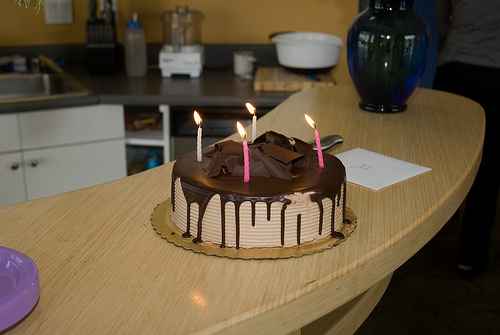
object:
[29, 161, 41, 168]
hardware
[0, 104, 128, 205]
cabinet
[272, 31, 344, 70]
bowl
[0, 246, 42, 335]
plastic plates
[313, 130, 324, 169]
candle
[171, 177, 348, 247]
icing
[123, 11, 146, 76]
baby bottle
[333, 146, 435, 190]
envelope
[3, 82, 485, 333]
bar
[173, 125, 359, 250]
birthday cake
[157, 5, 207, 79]
food processor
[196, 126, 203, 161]
candle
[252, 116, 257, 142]
candle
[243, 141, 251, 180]
candle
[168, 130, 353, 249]
chocolate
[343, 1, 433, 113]
vase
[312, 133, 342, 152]
handle